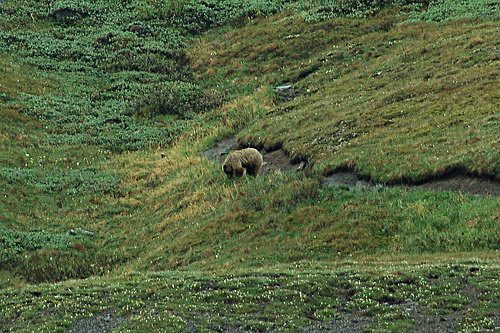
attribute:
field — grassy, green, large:
[1, 2, 484, 330]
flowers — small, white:
[457, 318, 484, 328]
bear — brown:
[221, 145, 265, 182]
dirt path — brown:
[205, 129, 498, 202]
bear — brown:
[217, 143, 266, 193]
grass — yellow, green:
[50, 72, 180, 286]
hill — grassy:
[255, 14, 498, 268]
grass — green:
[21, 74, 166, 175]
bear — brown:
[213, 141, 271, 186]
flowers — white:
[348, 274, 397, 315]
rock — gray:
[273, 75, 294, 98]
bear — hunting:
[212, 141, 275, 184]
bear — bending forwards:
[217, 141, 267, 186]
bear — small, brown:
[217, 141, 266, 182]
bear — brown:
[213, 137, 269, 187]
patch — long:
[246, 132, 498, 201]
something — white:
[272, 79, 297, 97]